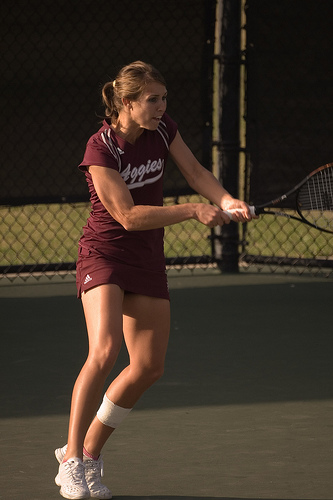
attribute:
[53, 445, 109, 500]
shoes — white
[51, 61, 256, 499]
woman — playing tennis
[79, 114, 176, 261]
jersey — maroon, red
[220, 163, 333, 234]
tennis racket — black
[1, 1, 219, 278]
fence — metal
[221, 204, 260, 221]
handle — white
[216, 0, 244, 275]
pole — metal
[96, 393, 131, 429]
bandage — white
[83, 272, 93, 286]
logo — white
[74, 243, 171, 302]
skirt — red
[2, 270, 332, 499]
ground — tennis court